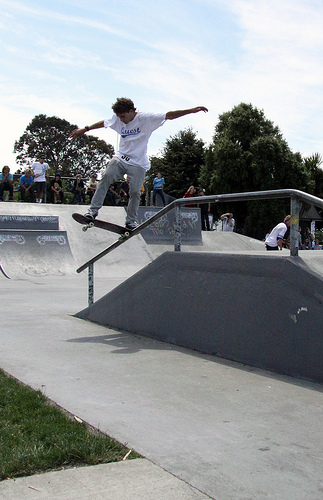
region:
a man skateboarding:
[60, 83, 203, 259]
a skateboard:
[66, 208, 169, 247]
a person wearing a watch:
[67, 71, 224, 237]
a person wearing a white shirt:
[49, 79, 204, 198]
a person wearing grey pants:
[80, 86, 201, 253]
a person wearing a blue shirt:
[7, 158, 51, 211]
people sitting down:
[2, 139, 200, 228]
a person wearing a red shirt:
[179, 175, 206, 209]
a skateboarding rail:
[48, 183, 322, 291]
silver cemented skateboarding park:
[0, 191, 315, 490]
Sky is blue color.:
[121, 11, 225, 41]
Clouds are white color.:
[256, 36, 306, 100]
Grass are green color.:
[14, 408, 75, 466]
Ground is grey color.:
[179, 420, 265, 481]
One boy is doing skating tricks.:
[68, 105, 157, 229]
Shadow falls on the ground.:
[71, 302, 187, 375]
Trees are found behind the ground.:
[33, 115, 265, 202]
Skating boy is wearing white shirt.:
[81, 99, 204, 132]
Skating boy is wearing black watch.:
[86, 124, 92, 132]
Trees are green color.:
[224, 141, 261, 167]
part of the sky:
[182, 10, 216, 39]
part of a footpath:
[175, 400, 218, 465]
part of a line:
[157, 465, 179, 485]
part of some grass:
[26, 430, 73, 464]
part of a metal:
[148, 206, 175, 234]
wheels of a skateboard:
[119, 228, 130, 239]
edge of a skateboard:
[106, 215, 119, 227]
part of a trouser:
[119, 167, 147, 190]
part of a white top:
[129, 140, 146, 155]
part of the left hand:
[193, 109, 209, 117]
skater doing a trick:
[68, 82, 205, 245]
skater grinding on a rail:
[56, 67, 201, 255]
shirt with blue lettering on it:
[90, 109, 173, 179]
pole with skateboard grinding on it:
[50, 187, 295, 309]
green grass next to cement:
[4, 362, 129, 463]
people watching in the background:
[3, 154, 94, 212]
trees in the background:
[191, 94, 308, 197]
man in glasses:
[35, 153, 54, 173]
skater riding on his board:
[263, 213, 295, 257]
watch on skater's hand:
[57, 116, 112, 146]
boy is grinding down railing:
[52, 62, 212, 241]